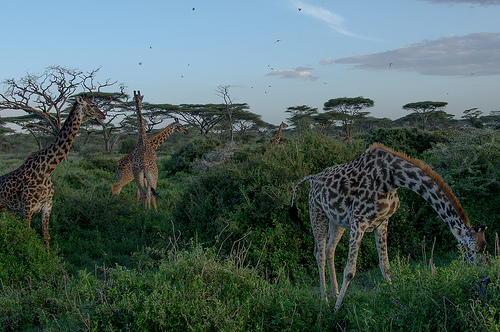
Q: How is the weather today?
A: It is cloudy.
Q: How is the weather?
A: It is cloudy.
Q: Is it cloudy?
A: Yes, it is cloudy.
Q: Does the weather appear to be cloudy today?
A: Yes, it is cloudy.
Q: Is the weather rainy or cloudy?
A: It is cloudy.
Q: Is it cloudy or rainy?
A: It is cloudy.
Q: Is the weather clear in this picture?
A: No, it is cloudy.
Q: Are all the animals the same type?
A: No, there are both giraffes and birds.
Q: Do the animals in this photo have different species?
A: Yes, they are giraffes and birds.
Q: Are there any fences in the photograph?
A: No, there are no fences.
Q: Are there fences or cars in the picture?
A: No, there are no fences or cars.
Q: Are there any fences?
A: No, there are no fences.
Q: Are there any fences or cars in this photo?
A: No, there are no fences or cars.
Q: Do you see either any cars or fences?
A: No, there are no fences or cars.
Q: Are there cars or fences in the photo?
A: No, there are no fences or cars.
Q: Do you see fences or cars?
A: No, there are no fences or cars.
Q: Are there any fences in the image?
A: No, there are no fences.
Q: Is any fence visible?
A: No, there are no fences.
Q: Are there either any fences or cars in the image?
A: No, there are no fences or cars.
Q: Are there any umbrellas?
A: No, there are no umbrellas.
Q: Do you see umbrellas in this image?
A: No, there are no umbrellas.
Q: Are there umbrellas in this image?
A: No, there are no umbrellas.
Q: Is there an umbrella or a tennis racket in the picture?
A: No, there are no umbrellas or rackets.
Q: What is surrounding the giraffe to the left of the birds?
A: The bush is surrounding the giraffe.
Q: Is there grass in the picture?
A: Yes, there is grass.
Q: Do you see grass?
A: Yes, there is grass.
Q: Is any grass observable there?
A: Yes, there is grass.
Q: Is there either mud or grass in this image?
A: Yes, there is grass.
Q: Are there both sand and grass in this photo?
A: No, there is grass but no sand.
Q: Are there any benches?
A: No, there are no benches.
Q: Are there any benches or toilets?
A: No, there are no benches or toilets.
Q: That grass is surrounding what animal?
A: The grass is surrounding the giraffe.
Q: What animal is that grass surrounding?
A: The grass is surrounding the giraffe.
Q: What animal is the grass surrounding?
A: The grass is surrounding the giraffe.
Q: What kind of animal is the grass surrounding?
A: The grass is surrounding the giraffe.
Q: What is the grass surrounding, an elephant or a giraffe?
A: The grass is surrounding a giraffe.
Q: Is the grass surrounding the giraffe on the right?
A: Yes, the grass is surrounding the giraffe.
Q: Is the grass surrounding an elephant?
A: No, the grass is surrounding the giraffe.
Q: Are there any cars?
A: No, there are no cars.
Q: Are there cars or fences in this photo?
A: No, there are no cars or fences.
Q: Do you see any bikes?
A: No, there are no bikes.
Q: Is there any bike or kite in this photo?
A: No, there are no bikes or kites.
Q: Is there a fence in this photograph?
A: No, there are no fences.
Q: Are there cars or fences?
A: No, there are no fences or cars.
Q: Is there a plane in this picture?
A: No, there are no airplanes.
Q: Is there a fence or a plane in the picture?
A: No, there are no airplanes or fences.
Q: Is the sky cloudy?
A: Yes, the sky is cloudy.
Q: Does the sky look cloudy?
A: Yes, the sky is cloudy.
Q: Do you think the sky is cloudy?
A: Yes, the sky is cloudy.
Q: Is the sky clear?
A: No, the sky is cloudy.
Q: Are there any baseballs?
A: No, there are no baseballs.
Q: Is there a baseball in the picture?
A: No, there are no baseballs.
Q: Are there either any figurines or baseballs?
A: No, there are no baseballs or figurines.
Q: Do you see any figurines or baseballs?
A: No, there are no baseballs or figurines.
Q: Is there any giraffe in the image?
A: Yes, there is a giraffe.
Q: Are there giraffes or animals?
A: Yes, there is a giraffe.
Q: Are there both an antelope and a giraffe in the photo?
A: No, there is a giraffe but no antelopes.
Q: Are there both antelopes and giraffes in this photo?
A: No, there is a giraffe but no antelopes.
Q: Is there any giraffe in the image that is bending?
A: Yes, there is a giraffe that is bending.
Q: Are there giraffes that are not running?
A: Yes, there is a giraffe that is bending.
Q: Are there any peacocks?
A: No, there are no peacocks.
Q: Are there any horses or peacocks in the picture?
A: No, there are no peacocks or horses.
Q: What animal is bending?
A: The animal is a giraffe.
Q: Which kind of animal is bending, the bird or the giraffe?
A: The giraffe is bending.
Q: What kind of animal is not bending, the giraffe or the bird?
A: The bird is not bending.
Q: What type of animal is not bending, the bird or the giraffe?
A: The bird is not bending.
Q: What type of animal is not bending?
A: The animal is a bird.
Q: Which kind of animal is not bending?
A: The animal is a bird.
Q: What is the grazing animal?
A: The animal is a giraffe.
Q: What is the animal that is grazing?
A: The animal is a giraffe.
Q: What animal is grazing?
A: The animal is a giraffe.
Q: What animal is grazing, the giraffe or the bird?
A: The giraffe is grazing.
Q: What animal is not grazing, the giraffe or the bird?
A: The bird is not grazing.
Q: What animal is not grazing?
A: The animal is a bird.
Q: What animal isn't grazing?
A: The animal is a bird.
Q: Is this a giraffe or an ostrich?
A: This is a giraffe.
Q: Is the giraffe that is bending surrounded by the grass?
A: Yes, the giraffe is surrounded by the grass.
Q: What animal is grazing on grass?
A: The giraffe is grazing on grass.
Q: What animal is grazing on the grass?
A: The giraffe is grazing on grass.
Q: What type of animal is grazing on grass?
A: The animal is a giraffe.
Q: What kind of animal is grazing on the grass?
A: The animal is a giraffe.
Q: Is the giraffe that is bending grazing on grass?
A: Yes, the giraffe is grazing on grass.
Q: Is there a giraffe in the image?
A: Yes, there is a giraffe.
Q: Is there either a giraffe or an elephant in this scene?
A: Yes, there is a giraffe.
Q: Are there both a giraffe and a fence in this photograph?
A: No, there is a giraffe but no fences.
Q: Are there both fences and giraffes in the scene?
A: No, there is a giraffe but no fences.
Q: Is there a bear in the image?
A: No, there are no bears.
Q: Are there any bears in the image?
A: No, there are no bears.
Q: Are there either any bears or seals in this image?
A: No, there are no bears or seals.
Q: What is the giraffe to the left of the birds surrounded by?
A: The giraffe is surrounded by the bush.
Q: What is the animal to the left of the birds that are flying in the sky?
A: The animal is a giraffe.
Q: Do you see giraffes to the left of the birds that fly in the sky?
A: Yes, there is a giraffe to the left of the birds.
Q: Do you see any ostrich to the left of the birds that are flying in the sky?
A: No, there is a giraffe to the left of the birds.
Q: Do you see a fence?
A: No, there are no fences.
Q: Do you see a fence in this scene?
A: No, there are no fences.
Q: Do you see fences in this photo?
A: No, there are no fences.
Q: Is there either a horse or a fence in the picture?
A: No, there are no fences or horses.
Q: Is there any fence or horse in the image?
A: No, there are no fences or horses.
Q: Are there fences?
A: No, there are no fences.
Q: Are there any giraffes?
A: Yes, there is a giraffe.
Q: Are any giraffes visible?
A: Yes, there is a giraffe.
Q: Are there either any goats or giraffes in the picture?
A: Yes, there is a giraffe.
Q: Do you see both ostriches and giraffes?
A: No, there is a giraffe but no ostriches.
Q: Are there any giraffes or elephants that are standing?
A: Yes, the giraffe is standing.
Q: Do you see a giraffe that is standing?
A: Yes, there is a giraffe that is standing.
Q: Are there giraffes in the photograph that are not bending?
A: Yes, there is a giraffe that is standing.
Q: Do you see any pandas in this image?
A: No, there are no pandas.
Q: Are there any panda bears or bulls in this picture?
A: No, there are no panda bears or bulls.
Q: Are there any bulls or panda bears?
A: No, there are no panda bears or bulls.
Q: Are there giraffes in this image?
A: Yes, there is a giraffe.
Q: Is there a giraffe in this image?
A: Yes, there is a giraffe.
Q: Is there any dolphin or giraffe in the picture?
A: Yes, there is a giraffe.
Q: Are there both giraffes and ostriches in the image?
A: No, there is a giraffe but no ostriches.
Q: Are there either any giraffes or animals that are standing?
A: Yes, the giraffe is standing.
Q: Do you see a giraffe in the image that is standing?
A: Yes, there is a giraffe that is standing.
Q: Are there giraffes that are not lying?
A: Yes, there is a giraffe that is standing.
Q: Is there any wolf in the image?
A: No, there are no wolves.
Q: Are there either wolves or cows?
A: No, there are no wolves or cows.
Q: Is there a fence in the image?
A: No, there are no fences.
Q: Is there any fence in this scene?
A: No, there are no fences.